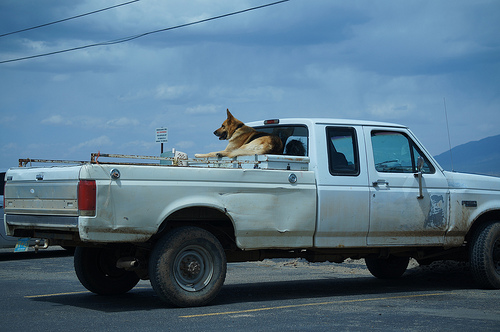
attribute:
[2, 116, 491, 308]
truck — white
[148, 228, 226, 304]
tire — black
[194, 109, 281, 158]
dog — lying, black, sitting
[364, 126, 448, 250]
door — white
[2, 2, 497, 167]
sky — cloudy, blue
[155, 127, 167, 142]
sign — red, tall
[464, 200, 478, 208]
emblem — silver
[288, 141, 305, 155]
person — sitting, driving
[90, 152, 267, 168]
rail — white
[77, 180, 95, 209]
taillight — red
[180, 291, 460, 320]
line — yellow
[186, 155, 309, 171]
container — gray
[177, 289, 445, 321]
stripe — yellow